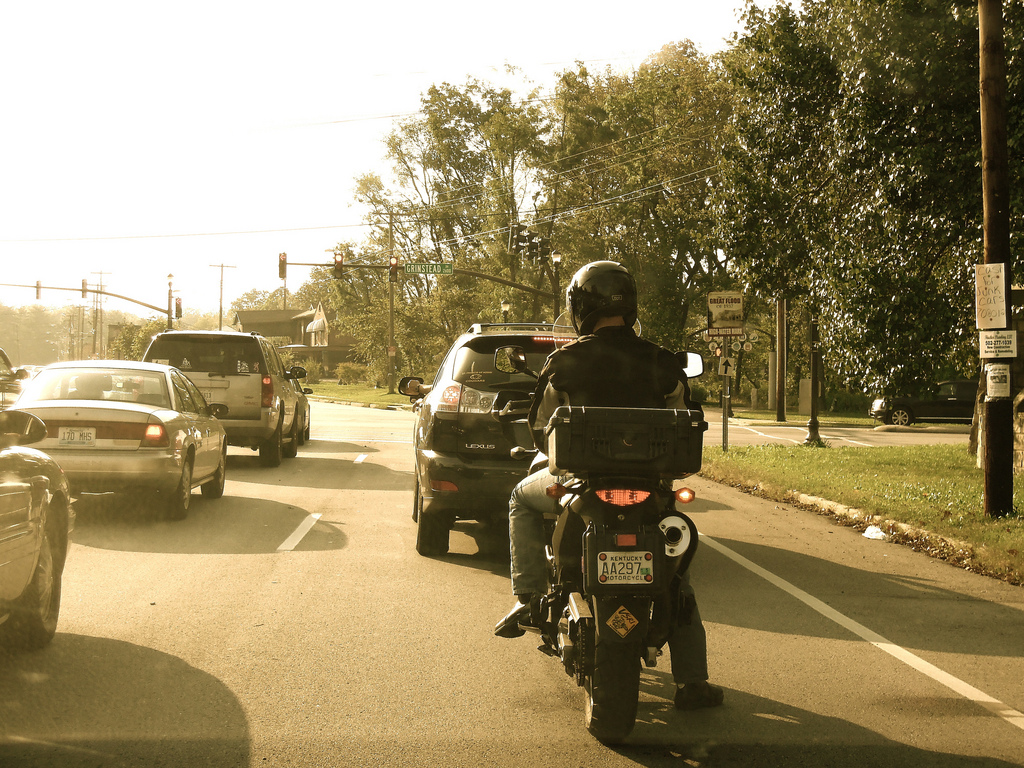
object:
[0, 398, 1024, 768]
road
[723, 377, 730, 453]
sign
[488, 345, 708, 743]
motorcycle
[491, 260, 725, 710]
person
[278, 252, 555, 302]
pole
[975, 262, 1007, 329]
sign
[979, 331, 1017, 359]
sign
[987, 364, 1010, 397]
sign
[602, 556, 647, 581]
characters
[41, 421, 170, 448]
brake light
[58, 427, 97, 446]
license plate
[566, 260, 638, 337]
head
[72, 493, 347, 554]
shadow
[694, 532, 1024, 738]
line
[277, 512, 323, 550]
dash marks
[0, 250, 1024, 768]
traffic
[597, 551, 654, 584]
license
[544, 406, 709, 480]
case